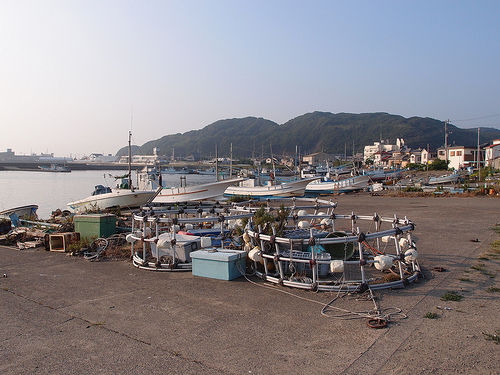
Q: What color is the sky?
A: Blue.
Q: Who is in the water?
A: No one.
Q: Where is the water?
A: On the left.